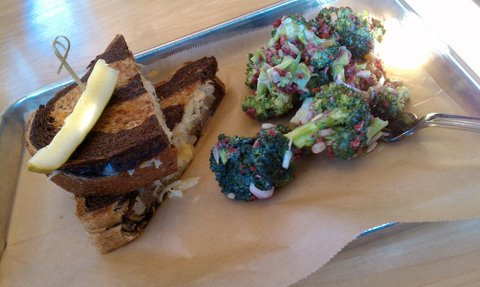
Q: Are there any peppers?
A: Yes, there are peppers.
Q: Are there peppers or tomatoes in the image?
A: Yes, there are peppers.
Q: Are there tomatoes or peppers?
A: Yes, there are peppers.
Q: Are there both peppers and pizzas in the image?
A: No, there are peppers but no pizzas.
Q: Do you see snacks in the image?
A: No, there are no snacks.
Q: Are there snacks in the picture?
A: No, there are no snacks.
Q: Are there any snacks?
A: No, there are no snacks.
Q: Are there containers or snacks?
A: No, there are no snacks or containers.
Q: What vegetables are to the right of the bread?
A: The vegetables are peppers.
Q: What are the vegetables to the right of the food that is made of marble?
A: The vegetables are peppers.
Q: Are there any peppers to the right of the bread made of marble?
A: Yes, there are peppers to the right of the bread.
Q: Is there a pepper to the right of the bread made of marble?
A: Yes, there are peppers to the right of the bread.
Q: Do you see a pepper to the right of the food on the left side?
A: Yes, there are peppers to the right of the bread.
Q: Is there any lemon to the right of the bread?
A: No, there are peppers to the right of the bread.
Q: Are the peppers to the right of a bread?
A: Yes, the peppers are to the right of a bread.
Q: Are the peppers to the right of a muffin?
A: No, the peppers are to the right of a bread.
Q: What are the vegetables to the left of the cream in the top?
A: The vegetables are peppers.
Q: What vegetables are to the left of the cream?
A: The vegetables are peppers.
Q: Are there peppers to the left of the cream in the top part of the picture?
A: Yes, there are peppers to the left of the cream.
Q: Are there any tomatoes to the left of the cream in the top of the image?
A: No, there are peppers to the left of the cream.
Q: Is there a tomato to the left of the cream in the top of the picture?
A: No, there are peppers to the left of the cream.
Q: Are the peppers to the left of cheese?
A: No, the peppers are to the left of the cream.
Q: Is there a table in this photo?
A: Yes, there is a table.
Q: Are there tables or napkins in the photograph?
A: Yes, there is a table.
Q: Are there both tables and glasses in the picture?
A: No, there is a table but no glasses.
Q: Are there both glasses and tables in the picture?
A: No, there is a table but no glasses.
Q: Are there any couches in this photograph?
A: No, there are no couches.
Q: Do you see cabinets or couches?
A: No, there are no couches or cabinets.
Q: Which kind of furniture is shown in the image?
A: The furniture is a table.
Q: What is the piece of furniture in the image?
A: The piece of furniture is a table.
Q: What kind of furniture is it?
A: The piece of furniture is a table.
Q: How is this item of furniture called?
A: This is a table.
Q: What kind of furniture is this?
A: This is a table.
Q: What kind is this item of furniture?
A: This is a table.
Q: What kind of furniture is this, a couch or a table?
A: This is a table.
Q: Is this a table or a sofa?
A: This is a table.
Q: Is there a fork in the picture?
A: Yes, there is a fork.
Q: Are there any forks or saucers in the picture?
A: Yes, there is a fork.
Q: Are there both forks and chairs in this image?
A: No, there is a fork but no chairs.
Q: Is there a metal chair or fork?
A: Yes, there is a metal fork.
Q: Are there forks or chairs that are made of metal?
A: Yes, the fork is made of metal.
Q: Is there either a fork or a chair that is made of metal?
A: Yes, the fork is made of metal.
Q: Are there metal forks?
A: Yes, there is a fork that is made of metal.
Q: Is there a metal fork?
A: Yes, there is a fork that is made of metal.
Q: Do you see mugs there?
A: No, there are no mugs.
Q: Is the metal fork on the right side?
A: Yes, the fork is on the right of the image.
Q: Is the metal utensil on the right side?
A: Yes, the fork is on the right of the image.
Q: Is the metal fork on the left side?
A: No, the fork is on the right of the image.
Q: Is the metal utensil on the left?
A: No, the fork is on the right of the image.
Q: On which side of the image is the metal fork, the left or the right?
A: The fork is on the right of the image.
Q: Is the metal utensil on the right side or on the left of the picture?
A: The fork is on the right of the image.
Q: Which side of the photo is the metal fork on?
A: The fork is on the right of the image.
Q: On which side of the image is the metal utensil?
A: The fork is on the right of the image.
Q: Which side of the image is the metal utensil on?
A: The fork is on the right of the image.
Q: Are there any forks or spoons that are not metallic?
A: No, there is a fork but it is metallic.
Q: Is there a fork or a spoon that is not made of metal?
A: No, there is a fork but it is made of metal.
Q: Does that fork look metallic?
A: Yes, the fork is metallic.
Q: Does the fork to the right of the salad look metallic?
A: Yes, the fork is metallic.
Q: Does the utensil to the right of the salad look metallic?
A: Yes, the fork is metallic.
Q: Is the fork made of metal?
A: Yes, the fork is made of metal.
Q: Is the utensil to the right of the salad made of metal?
A: Yes, the fork is made of metal.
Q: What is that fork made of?
A: The fork is made of metal.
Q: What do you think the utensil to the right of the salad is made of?
A: The fork is made of metal.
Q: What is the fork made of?
A: The fork is made of metal.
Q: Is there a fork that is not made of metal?
A: No, there is a fork but it is made of metal.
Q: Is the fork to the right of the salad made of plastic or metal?
A: The fork is made of metal.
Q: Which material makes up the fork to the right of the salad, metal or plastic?
A: The fork is made of metal.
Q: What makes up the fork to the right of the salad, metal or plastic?
A: The fork is made of metal.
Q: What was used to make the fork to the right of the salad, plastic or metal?
A: The fork is made of metal.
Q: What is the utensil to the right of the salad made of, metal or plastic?
A: The fork is made of metal.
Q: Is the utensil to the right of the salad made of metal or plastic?
A: The fork is made of metal.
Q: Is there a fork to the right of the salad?
A: Yes, there is a fork to the right of the salad.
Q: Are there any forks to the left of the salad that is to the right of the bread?
A: No, the fork is to the right of the salad.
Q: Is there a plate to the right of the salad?
A: No, there is a fork to the right of the salad.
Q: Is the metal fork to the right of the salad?
A: Yes, the fork is to the right of the salad.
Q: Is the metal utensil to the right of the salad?
A: Yes, the fork is to the right of the salad.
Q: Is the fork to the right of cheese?
A: No, the fork is to the right of the salad.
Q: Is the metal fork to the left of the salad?
A: No, the fork is to the right of the salad.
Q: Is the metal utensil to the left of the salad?
A: No, the fork is to the right of the salad.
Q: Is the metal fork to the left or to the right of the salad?
A: The fork is to the right of the salad.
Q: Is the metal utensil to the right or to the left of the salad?
A: The fork is to the right of the salad.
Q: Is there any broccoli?
A: Yes, there is broccoli.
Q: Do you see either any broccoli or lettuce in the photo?
A: Yes, there is broccoli.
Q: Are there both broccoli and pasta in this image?
A: No, there is broccoli but no pasta.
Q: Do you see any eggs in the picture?
A: No, there are no eggs.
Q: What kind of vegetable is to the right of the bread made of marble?
A: The vegetable is broccoli.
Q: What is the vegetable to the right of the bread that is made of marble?
A: The vegetable is broccoli.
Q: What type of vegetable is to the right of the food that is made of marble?
A: The vegetable is broccoli.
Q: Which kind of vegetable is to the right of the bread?
A: The vegetable is broccoli.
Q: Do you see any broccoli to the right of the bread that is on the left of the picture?
A: Yes, there is broccoli to the right of the bread.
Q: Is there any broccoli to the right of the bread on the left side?
A: Yes, there is broccoli to the right of the bread.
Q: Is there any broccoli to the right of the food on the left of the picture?
A: Yes, there is broccoli to the right of the bread.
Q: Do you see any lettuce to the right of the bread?
A: No, there is broccoli to the right of the bread.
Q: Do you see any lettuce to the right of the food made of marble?
A: No, there is broccoli to the right of the bread.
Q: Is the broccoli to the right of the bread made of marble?
A: Yes, the broccoli is to the right of the bread.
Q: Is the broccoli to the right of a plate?
A: No, the broccoli is to the right of the bread.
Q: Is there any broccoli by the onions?
A: Yes, there is broccoli by the onions.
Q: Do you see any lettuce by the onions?
A: No, there is broccoli by the onions.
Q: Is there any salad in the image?
A: Yes, there is salad.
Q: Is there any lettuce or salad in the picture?
A: Yes, there is salad.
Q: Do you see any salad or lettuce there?
A: Yes, there is salad.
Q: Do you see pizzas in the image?
A: No, there are no pizzas.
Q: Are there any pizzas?
A: No, there are no pizzas.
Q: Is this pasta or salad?
A: This is salad.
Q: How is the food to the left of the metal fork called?
A: The food is salad.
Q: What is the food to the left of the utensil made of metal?
A: The food is salad.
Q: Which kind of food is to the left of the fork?
A: The food is salad.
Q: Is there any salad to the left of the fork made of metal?
A: Yes, there is salad to the left of the fork.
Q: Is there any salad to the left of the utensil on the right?
A: Yes, there is salad to the left of the fork.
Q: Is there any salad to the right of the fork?
A: No, the salad is to the left of the fork.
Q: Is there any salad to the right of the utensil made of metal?
A: No, the salad is to the left of the fork.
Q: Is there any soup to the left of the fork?
A: No, there is salad to the left of the fork.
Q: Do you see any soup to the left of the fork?
A: No, there is salad to the left of the fork.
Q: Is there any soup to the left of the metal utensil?
A: No, there is salad to the left of the fork.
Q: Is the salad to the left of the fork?
A: Yes, the salad is to the left of the fork.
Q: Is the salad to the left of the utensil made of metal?
A: Yes, the salad is to the left of the fork.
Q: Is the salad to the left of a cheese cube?
A: No, the salad is to the left of the fork.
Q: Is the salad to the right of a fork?
A: No, the salad is to the left of a fork.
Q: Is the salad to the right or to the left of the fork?
A: The salad is to the left of the fork.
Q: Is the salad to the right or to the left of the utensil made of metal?
A: The salad is to the left of the fork.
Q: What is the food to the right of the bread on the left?
A: The food is salad.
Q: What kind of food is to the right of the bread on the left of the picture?
A: The food is salad.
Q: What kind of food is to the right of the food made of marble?
A: The food is salad.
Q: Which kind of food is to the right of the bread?
A: The food is salad.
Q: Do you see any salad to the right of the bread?
A: Yes, there is salad to the right of the bread.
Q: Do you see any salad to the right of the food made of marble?
A: Yes, there is salad to the right of the bread.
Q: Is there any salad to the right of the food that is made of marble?
A: Yes, there is salad to the right of the bread.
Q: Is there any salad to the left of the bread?
A: No, the salad is to the right of the bread.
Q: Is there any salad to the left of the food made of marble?
A: No, the salad is to the right of the bread.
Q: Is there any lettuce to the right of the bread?
A: No, there is salad to the right of the bread.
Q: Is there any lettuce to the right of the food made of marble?
A: No, there is salad to the right of the bread.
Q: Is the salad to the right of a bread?
A: Yes, the salad is to the right of a bread.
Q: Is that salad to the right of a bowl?
A: No, the salad is to the right of a bread.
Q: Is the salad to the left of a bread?
A: No, the salad is to the right of a bread.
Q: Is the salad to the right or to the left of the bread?
A: The salad is to the right of the bread.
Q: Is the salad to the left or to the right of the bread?
A: The salad is to the right of the bread.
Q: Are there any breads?
A: Yes, there is a bread.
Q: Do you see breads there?
A: Yes, there is a bread.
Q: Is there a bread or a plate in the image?
A: Yes, there is a bread.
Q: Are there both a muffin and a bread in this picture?
A: No, there is a bread but no muffins.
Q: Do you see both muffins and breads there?
A: No, there is a bread but no muffins.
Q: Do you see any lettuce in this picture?
A: No, there is no lettuce.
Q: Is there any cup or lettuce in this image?
A: No, there are no lettuce or cups.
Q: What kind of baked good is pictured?
A: The baked good is a bread.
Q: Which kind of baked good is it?
A: The food is a bread.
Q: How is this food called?
A: This is a bread.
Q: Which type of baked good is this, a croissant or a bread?
A: This is a bread.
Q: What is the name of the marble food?
A: The food is a bread.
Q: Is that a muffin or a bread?
A: That is a bread.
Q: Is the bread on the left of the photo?
A: Yes, the bread is on the left of the image.